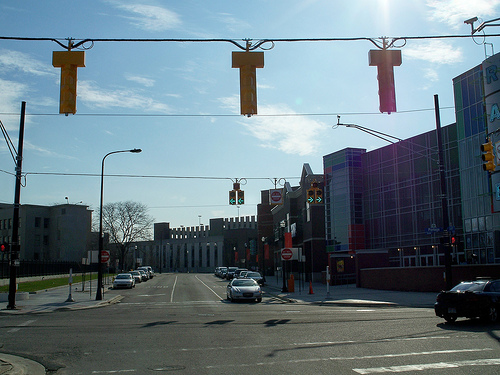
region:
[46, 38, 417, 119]
3 t shaped traffic lights hanging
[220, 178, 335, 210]
2 traffic lights with green arrows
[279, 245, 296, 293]
do not enter sign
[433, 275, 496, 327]
the car is turning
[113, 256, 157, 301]
cars parked in a row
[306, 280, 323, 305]
orange cone on the side walk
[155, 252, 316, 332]
car on the street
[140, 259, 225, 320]
vertical lines on the street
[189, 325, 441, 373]
horizontal lines on the street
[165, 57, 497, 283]
multiple building on the side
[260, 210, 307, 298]
sign on a pole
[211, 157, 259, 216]
this is a street light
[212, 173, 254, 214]
green arrows on street light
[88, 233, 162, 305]
cars parked on side of road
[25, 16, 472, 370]
a bright and clear day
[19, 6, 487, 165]
multiple street lights on line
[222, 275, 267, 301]
white car on the road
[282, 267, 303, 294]
orange cone on the sidewalk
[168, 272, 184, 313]
white lines on the street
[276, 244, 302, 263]
red and white sign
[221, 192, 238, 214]
green signal in traffic signal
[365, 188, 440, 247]
large window panes in front of building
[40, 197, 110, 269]
tall square building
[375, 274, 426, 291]
red paint on side of the wall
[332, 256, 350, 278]
yellow symbol on side of wall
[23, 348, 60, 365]
cracks in the sidewalk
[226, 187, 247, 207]
Two green arrows on traffic lights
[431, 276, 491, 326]
The back of a car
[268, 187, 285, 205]
Red and white street sign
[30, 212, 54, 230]
Two windows on a building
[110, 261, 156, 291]
Cars parked on side of a street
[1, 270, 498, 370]
White lines on the street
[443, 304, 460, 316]
A white license plate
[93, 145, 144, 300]
A tall street lamp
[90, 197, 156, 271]
A tree with no leaves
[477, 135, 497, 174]
A yellow traffic light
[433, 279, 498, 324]
Black car turning right in the road.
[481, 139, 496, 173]
Yellow traffic light over a black car turning.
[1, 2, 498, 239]
Blue sky with white clouds.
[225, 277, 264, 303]
A silver car stopped at the traffic light.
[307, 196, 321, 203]
Two green arrows pointing right.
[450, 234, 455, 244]
Orange hand on a pole by a black car.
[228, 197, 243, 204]
Two green arrows pointing left.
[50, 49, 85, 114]
Left most yellow T shaped traffic light.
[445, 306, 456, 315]
White license plate on the back of a black car.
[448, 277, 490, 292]
Back windshield of a black car.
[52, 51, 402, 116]
a set of three traffic lights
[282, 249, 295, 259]
a do not enter sign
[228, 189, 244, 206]
two street lights with left green arrows